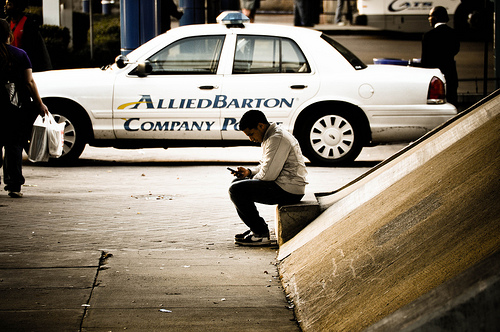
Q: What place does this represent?
A: It represents the sidewalk.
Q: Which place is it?
A: It is a sidewalk.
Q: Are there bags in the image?
A: Yes, there is a bag.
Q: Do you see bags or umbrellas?
A: Yes, there is a bag.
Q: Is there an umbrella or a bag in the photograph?
A: Yes, there is a bag.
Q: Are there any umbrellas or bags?
A: Yes, there is a bag.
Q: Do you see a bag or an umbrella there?
A: Yes, there is a bag.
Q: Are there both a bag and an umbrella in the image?
A: No, there is a bag but no umbrellas.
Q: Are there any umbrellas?
A: No, there are no umbrellas.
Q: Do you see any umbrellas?
A: No, there are no umbrellas.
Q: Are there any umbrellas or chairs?
A: No, there are no umbrellas or chairs.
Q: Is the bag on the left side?
A: Yes, the bag is on the left of the image.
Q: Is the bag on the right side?
A: No, the bag is on the left of the image.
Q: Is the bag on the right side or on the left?
A: The bag is on the left of the image.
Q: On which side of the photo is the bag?
A: The bag is on the left of the image.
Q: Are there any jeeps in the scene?
A: No, there are no jeeps.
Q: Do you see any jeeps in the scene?
A: No, there are no jeeps.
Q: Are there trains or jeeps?
A: No, there are no jeeps or trains.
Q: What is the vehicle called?
A: The vehicle is a car.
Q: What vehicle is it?
A: The vehicle is a car.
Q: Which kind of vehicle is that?
A: This is a car.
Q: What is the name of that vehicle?
A: This is a car.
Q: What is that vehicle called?
A: This is a car.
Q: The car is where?
A: The car is on the road.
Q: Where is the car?
A: The car is on the road.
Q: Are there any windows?
A: Yes, there is a window.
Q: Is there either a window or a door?
A: Yes, there is a window.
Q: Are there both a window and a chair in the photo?
A: No, there is a window but no chairs.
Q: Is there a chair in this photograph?
A: No, there are no chairs.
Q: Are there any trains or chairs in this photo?
A: No, there are no chairs or trains.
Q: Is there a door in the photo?
A: Yes, there is a door.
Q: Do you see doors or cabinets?
A: Yes, there is a door.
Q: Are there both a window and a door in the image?
A: Yes, there are both a door and a window.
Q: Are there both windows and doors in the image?
A: Yes, there are both a door and a window.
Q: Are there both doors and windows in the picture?
A: Yes, there are both a door and a window.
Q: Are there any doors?
A: Yes, there is a door.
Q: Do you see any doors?
A: Yes, there is a door.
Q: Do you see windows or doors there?
A: Yes, there is a door.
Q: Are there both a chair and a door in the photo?
A: No, there is a door but no chairs.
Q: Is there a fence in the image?
A: No, there are no fences.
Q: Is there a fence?
A: No, there are no fences.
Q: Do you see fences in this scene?
A: No, there are no fences.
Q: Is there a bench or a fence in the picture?
A: No, there are no fences or benches.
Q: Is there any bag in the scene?
A: Yes, there is a bag.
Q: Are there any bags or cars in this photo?
A: Yes, there is a bag.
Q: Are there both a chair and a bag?
A: No, there is a bag but no chairs.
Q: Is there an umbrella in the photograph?
A: No, there are no umbrellas.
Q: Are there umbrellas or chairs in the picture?
A: No, there are no umbrellas or chairs.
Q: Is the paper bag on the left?
A: Yes, the bag is on the left of the image.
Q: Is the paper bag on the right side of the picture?
A: No, the bag is on the left of the image.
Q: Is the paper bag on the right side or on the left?
A: The bag is on the left of the image.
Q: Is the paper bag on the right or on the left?
A: The bag is on the left of the image.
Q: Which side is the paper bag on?
A: The bag is on the left of the image.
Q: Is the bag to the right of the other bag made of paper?
A: Yes, the bag is made of paper.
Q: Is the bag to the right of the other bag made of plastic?
A: No, the bag is made of paper.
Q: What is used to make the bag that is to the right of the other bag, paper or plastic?
A: The bag is made of paper.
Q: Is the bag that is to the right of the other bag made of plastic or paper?
A: The bag is made of paper.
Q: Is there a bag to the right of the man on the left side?
A: Yes, there is a bag to the right of the man.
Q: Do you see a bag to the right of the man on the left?
A: Yes, there is a bag to the right of the man.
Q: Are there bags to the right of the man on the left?
A: Yes, there is a bag to the right of the man.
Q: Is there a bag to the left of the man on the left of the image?
A: No, the bag is to the right of the man.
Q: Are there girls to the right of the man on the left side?
A: No, there is a bag to the right of the man.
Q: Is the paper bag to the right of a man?
A: Yes, the bag is to the right of a man.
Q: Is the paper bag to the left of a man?
A: No, the bag is to the right of a man.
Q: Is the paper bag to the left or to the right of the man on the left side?
A: The bag is to the right of the man.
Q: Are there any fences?
A: No, there are no fences.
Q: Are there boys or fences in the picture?
A: No, there are no fences or boys.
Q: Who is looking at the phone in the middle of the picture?
A: The man is looking at the phone.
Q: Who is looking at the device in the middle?
A: The man is looking at the phone.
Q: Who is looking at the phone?
A: The man is looking at the phone.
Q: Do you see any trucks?
A: No, there are no trucks.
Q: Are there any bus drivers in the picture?
A: No, there are no bus drivers.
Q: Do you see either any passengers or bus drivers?
A: No, there are no bus drivers or passengers.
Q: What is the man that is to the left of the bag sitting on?
A: The man is sitting on the sidewalk.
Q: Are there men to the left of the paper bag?
A: Yes, there is a man to the left of the bag.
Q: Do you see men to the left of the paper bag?
A: Yes, there is a man to the left of the bag.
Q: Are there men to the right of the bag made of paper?
A: No, the man is to the left of the bag.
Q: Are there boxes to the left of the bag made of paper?
A: No, there is a man to the left of the bag.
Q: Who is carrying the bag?
A: The man is carrying the bag.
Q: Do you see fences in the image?
A: No, there are no fences.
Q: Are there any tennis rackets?
A: No, there are no tennis rackets.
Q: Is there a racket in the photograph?
A: No, there are no rackets.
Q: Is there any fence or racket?
A: No, there are no rackets or fences.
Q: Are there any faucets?
A: No, there are no faucets.